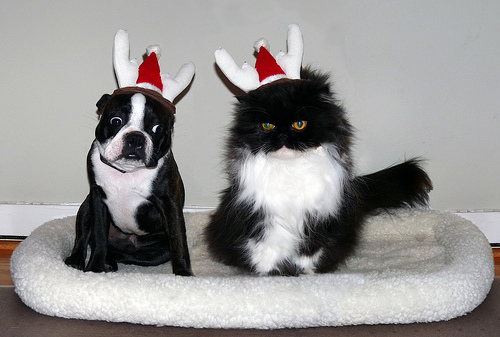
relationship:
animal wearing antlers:
[65, 93, 193, 276] [112, 30, 198, 115]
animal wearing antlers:
[199, 64, 432, 276] [214, 24, 303, 95]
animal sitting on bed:
[65, 93, 193, 276] [9, 211, 494, 330]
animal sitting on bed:
[199, 64, 432, 276] [9, 211, 494, 330]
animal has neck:
[199, 64, 432, 276] [235, 145, 345, 167]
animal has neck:
[65, 93, 193, 276] [91, 141, 174, 174]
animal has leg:
[65, 93, 193, 276] [65, 194, 93, 271]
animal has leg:
[65, 93, 193, 276] [84, 181, 107, 271]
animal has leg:
[65, 93, 193, 276] [157, 193, 191, 275]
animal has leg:
[65, 93, 193, 276] [103, 255, 117, 272]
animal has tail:
[199, 64, 432, 276] [354, 158, 433, 215]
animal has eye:
[65, 93, 193, 276] [108, 116, 121, 126]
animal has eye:
[65, 93, 193, 276] [152, 124, 162, 134]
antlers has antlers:
[112, 30, 198, 115] [114, 29, 196, 102]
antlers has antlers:
[214, 24, 303, 95] [214, 24, 303, 92]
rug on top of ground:
[0, 276, 499, 337] [0, 240, 498, 287]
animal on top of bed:
[65, 93, 193, 276] [9, 211, 494, 330]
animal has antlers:
[65, 93, 193, 276] [112, 30, 198, 115]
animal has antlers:
[199, 64, 432, 276] [214, 24, 303, 95]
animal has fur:
[199, 64, 432, 276] [195, 65, 433, 275]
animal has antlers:
[65, 93, 193, 276] [114, 29, 196, 102]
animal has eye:
[199, 64, 432, 276] [261, 121, 275, 130]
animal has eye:
[199, 64, 432, 276] [293, 121, 305, 130]